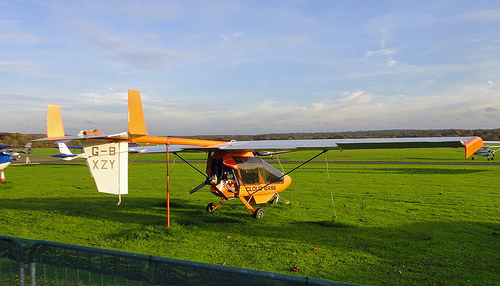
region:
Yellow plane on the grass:
[21, 86, 491, 223]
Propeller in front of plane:
[171, 149, 236, 213]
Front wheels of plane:
[196, 197, 267, 222]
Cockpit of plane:
[219, 151, 306, 206]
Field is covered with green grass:
[8, 144, 496, 279]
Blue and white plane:
[47, 143, 90, 165]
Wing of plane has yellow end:
[229, 134, 491, 161]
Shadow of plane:
[265, 213, 498, 275]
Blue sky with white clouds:
[3, 1, 498, 133]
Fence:
[11, 236, 338, 283]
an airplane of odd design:
[27, 86, 483, 240]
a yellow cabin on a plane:
[192, 152, 301, 214]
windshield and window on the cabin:
[236, 153, 283, 183]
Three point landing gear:
[200, 195, 312, 223]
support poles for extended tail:
[110, 132, 175, 229]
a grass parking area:
[70, 159, 498, 274]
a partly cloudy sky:
[0, 0, 493, 135]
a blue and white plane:
[0, 137, 31, 184]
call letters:
[80, 140, 120, 173]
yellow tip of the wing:
[432, 127, 490, 171]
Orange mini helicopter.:
[20, 131, 484, 218]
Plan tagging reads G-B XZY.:
[80, 134, 130, 205]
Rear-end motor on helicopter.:
[197, 161, 242, 193]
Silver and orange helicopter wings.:
[93, 132, 488, 159]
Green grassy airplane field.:
[317, 163, 497, 272]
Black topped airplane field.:
[323, 159, 498, 168]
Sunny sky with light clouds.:
[172, 59, 490, 134]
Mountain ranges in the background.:
[285, 129, 498, 137]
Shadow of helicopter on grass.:
[12, 192, 207, 239]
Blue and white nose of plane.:
[0, 154, 11, 172]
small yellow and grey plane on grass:
[37, 93, 493, 223]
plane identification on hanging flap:
[61, 120, 141, 210]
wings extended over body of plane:
[30, 81, 480, 167]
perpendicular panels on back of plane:
[40, 80, 157, 150]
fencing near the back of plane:
[11, 231, 296, 281]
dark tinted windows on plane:
[212, 152, 293, 222]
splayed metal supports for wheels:
[191, 185, 271, 225]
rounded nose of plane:
[275, 165, 300, 190]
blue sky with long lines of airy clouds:
[265, 10, 487, 111]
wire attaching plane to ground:
[310, 141, 345, 236]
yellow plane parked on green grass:
[40, 87, 485, 226]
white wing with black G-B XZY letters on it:
[77, 120, 136, 207]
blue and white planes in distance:
[1, 130, 150, 187]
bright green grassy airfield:
[8, 135, 499, 285]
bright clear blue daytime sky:
[8, 0, 498, 153]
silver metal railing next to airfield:
[0, 229, 414, 279]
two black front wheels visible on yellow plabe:
[201, 200, 270, 220]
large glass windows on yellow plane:
[229, 154, 288, 190]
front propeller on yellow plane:
[181, 159, 247, 201]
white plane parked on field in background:
[463, 137, 498, 169]